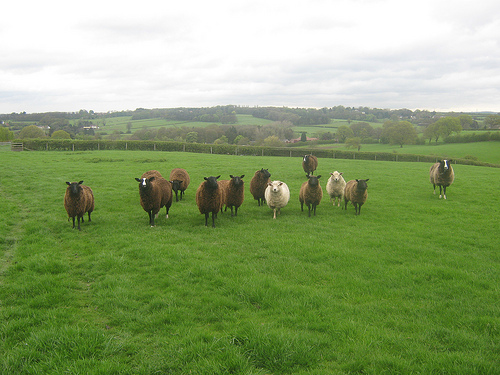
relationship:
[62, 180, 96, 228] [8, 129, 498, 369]
sheep standing in field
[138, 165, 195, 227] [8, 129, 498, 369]
sheep standing in field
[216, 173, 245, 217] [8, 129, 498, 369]
sheep standing in field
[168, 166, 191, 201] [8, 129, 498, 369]
sheep standing in field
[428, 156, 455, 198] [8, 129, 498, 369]
sheep standing in field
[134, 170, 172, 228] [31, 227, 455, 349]
sheep standing in field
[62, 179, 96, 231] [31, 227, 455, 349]
sheep standing in field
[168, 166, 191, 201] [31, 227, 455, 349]
sheep standing in field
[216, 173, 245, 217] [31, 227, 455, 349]
sheep standing in field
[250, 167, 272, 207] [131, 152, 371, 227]
sheep in flock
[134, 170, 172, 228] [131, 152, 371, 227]
sheep in flock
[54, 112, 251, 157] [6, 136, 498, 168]
hedges along fence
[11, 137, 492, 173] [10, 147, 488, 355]
fence surrounding field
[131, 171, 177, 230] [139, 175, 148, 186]
sheep has face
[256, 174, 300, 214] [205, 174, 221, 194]
sheep has face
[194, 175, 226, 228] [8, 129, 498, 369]
sheep walking in field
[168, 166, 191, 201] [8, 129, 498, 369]
sheep in field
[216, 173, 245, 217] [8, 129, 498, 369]
sheep in field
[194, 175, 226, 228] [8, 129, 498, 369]
sheep in field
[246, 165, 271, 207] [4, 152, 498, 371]
sheep in grass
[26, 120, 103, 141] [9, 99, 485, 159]
house in distance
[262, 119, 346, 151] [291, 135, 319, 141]
house has roof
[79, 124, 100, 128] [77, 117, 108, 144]
roof of building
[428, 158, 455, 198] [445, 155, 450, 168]
sheep with stripe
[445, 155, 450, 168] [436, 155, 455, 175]
stripe on face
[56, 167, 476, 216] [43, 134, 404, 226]
herd of sheep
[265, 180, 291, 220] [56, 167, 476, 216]
sheep of herd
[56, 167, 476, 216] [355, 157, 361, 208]
herd of sheep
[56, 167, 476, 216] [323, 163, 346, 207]
herd of sheep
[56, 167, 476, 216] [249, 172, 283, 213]
herd of sheep